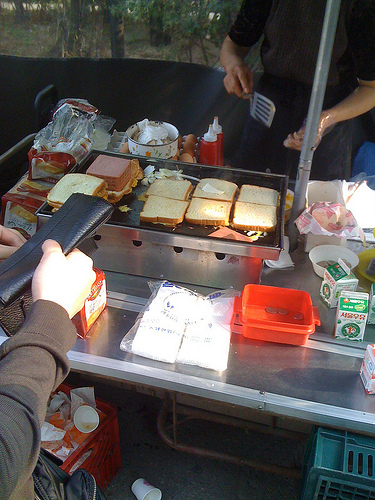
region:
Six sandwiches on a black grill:
[134, 172, 283, 252]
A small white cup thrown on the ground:
[131, 469, 158, 498]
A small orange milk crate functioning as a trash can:
[28, 386, 131, 495]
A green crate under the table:
[308, 429, 368, 498]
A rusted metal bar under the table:
[154, 411, 297, 485]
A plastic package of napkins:
[134, 281, 235, 375]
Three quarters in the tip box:
[260, 300, 307, 321]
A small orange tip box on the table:
[230, 283, 331, 351]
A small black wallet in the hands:
[0, 192, 124, 308]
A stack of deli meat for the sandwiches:
[91, 153, 141, 195]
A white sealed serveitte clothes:
[133, 277, 179, 353]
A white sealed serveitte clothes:
[194, 297, 221, 373]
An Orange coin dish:
[241, 286, 307, 345]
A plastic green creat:
[310, 445, 363, 499]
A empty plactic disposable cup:
[125, 472, 165, 496]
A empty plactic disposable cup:
[77, 407, 102, 437]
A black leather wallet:
[3, 208, 110, 291]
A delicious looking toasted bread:
[143, 176, 183, 225]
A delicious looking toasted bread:
[193, 194, 228, 227]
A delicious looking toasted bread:
[242, 179, 269, 230]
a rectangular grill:
[41, 144, 287, 287]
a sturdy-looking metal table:
[2, 181, 373, 429]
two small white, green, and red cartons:
[319, 254, 371, 341]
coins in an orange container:
[232, 279, 322, 345]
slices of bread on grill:
[139, 170, 282, 238]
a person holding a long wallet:
[0, 190, 111, 497]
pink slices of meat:
[87, 153, 135, 192]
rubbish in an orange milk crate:
[39, 380, 121, 485]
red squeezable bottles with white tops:
[198, 113, 224, 167]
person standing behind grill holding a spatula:
[38, 0, 372, 285]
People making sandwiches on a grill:
[4, 53, 363, 485]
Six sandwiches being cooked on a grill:
[141, 173, 279, 235]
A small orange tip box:
[228, 278, 321, 348]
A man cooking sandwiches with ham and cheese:
[174, 74, 370, 265]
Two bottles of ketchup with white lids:
[198, 114, 238, 170]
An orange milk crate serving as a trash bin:
[19, 383, 121, 489]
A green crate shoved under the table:
[303, 437, 372, 499]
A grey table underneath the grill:
[53, 305, 373, 423]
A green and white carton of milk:
[327, 287, 369, 351]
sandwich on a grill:
[230, 197, 279, 235]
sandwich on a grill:
[182, 195, 237, 227]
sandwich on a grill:
[138, 193, 193, 226]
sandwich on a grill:
[141, 174, 195, 200]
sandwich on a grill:
[189, 171, 243, 204]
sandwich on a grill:
[230, 179, 285, 210]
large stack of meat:
[81, 152, 137, 191]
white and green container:
[328, 286, 373, 345]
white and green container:
[313, 257, 362, 305]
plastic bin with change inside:
[232, 279, 323, 345]